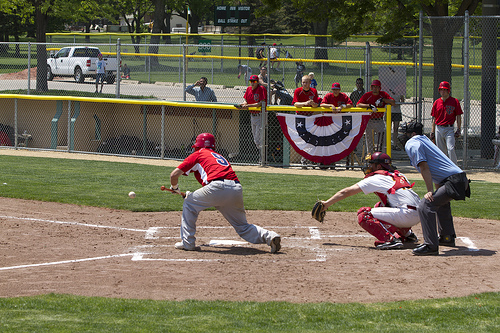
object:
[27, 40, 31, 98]
pole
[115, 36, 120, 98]
pole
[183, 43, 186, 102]
pole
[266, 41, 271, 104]
pole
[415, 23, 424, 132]
pole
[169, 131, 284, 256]
batter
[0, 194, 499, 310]
dirt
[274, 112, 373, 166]
banner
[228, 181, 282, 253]
leg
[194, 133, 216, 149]
helmet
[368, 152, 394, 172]
red helmet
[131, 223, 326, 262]
lines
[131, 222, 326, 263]
batter's box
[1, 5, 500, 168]
fence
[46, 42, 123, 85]
truck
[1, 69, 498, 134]
road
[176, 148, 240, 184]
jersey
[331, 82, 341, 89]
ball cap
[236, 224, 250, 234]
knee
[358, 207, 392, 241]
red shinguards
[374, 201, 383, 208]
red shinguards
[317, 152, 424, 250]
catcher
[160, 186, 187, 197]
bat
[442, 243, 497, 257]
shadow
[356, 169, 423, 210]
shirt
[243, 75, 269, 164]
player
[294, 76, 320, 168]
player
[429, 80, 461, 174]
player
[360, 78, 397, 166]
player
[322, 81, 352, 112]
player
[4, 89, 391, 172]
dugout